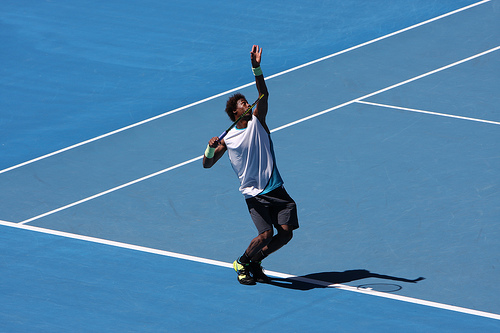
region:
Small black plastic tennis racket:
[216, 92, 269, 143]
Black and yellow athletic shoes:
[231, 260, 269, 284]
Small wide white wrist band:
[205, 142, 217, 159]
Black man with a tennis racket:
[202, 45, 300, 284]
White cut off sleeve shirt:
[219, 115, 283, 194]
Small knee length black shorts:
[244, 184, 299, 229]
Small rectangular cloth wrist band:
[251, 65, 260, 77]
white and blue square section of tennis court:
[357, 43, 497, 127]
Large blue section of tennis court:
[21, 100, 499, 316]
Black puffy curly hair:
[224, 93, 244, 120]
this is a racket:
[199, 90, 279, 140]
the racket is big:
[198, 83, 274, 143]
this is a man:
[178, 40, 315, 285]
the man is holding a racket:
[203, 84, 272, 141]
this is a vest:
[241, 150, 278, 183]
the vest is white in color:
[234, 153, 254, 168]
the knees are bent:
[244, 214, 301, 260]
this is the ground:
[21, 268, 93, 315]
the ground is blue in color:
[99, 275, 211, 318]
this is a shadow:
[290, 238, 445, 310]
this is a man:
[179, 40, 302, 270]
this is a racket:
[224, 110, 269, 139]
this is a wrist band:
[242, 66, 274, 78]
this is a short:
[266, 193, 294, 231]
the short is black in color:
[278, 198, 300, 218]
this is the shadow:
[288, 250, 385, 297]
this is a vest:
[247, 132, 275, 182]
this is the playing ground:
[381, 38, 468, 187]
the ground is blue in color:
[377, 148, 449, 223]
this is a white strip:
[388, 83, 475, 153]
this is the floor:
[57, 63, 114, 93]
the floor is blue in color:
[91, 50, 151, 82]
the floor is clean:
[29, 40, 110, 75]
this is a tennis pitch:
[14, 161, 169, 211]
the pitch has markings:
[31, 150, 105, 235]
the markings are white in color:
[14, 164, 89, 235]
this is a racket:
[217, 93, 267, 130]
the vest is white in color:
[246, 128, 273, 175]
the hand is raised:
[244, 39, 301, 121]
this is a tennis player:
[184, 55, 309, 295]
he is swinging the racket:
[195, 43, 312, 273]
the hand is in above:
[244, 38, 275, 80]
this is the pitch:
[85, 245, 159, 325]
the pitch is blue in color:
[80, 263, 176, 329]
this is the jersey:
[239, 143, 264, 180]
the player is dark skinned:
[249, 232, 266, 248]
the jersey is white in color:
[240, 135, 270, 174]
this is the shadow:
[300, 257, 412, 305]